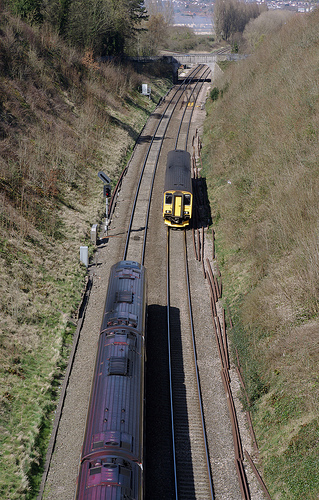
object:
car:
[162, 149, 194, 230]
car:
[75, 260, 146, 497]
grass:
[197, 0, 319, 499]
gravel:
[199, 246, 214, 274]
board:
[212, 229, 214, 259]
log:
[206, 258, 218, 302]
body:
[174, 8, 204, 29]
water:
[139, 0, 215, 33]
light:
[166, 210, 171, 213]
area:
[74, 221, 114, 312]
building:
[145, 0, 319, 13]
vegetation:
[217, 104, 289, 247]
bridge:
[93, 53, 250, 71]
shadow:
[180, 177, 212, 230]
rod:
[222, 308, 229, 368]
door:
[172, 192, 183, 218]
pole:
[106, 198, 108, 226]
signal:
[106, 192, 109, 195]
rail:
[40, 63, 215, 497]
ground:
[0, 17, 319, 498]